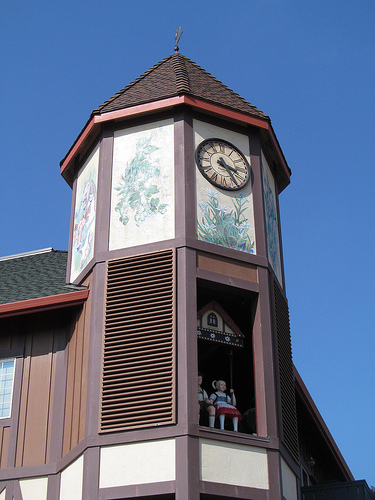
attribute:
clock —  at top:
[191, 135, 252, 192]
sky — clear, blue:
[209, 5, 371, 90]